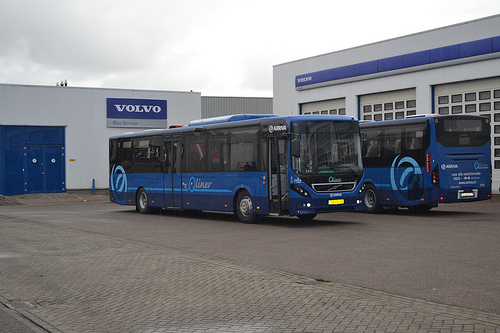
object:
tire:
[227, 192, 260, 222]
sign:
[106, 98, 168, 128]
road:
[0, 198, 500, 332]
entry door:
[267, 128, 289, 215]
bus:
[103, 113, 372, 223]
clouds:
[0, 0, 500, 89]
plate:
[458, 188, 477, 199]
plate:
[327, 198, 345, 205]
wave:
[103, 112, 368, 220]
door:
[430, 115, 497, 203]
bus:
[354, 115, 495, 212]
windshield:
[284, 118, 362, 177]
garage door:
[352, 87, 424, 124]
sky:
[1, 1, 498, 97]